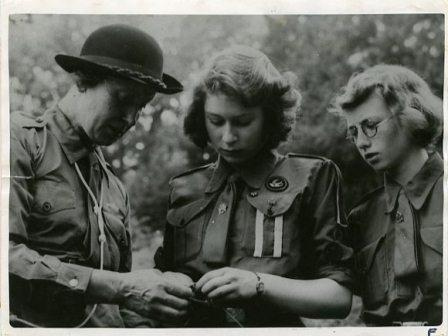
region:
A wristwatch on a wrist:
[247, 269, 270, 303]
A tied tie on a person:
[194, 155, 256, 272]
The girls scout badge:
[262, 171, 294, 195]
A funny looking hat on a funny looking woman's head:
[50, 39, 185, 156]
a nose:
[220, 119, 244, 148]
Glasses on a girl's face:
[344, 115, 379, 143]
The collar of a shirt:
[201, 147, 289, 198]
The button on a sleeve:
[66, 273, 80, 292]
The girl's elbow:
[319, 280, 356, 322]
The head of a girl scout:
[331, 64, 447, 190]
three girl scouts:
[11, 21, 446, 331]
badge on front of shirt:
[263, 171, 293, 193]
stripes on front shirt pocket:
[246, 204, 290, 260]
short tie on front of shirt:
[193, 171, 244, 267]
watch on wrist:
[243, 268, 266, 300]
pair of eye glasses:
[339, 104, 404, 148]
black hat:
[44, 21, 187, 99]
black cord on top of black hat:
[93, 58, 173, 92]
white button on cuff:
[62, 272, 82, 291]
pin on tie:
[213, 199, 231, 219]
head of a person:
[57, 26, 168, 152]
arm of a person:
[248, 277, 347, 324]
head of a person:
[168, 45, 311, 175]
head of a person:
[338, 83, 426, 168]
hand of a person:
[140, 247, 209, 314]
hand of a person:
[183, 250, 260, 318]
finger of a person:
[153, 275, 199, 330]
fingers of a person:
[209, 257, 246, 307]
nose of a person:
[125, 110, 142, 122]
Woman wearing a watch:
[241, 263, 265, 305]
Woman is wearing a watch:
[250, 264, 267, 305]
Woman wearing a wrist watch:
[247, 267, 266, 302]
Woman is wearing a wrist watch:
[245, 264, 268, 303]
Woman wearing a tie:
[382, 182, 427, 282]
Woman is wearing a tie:
[390, 184, 422, 288]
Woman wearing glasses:
[342, 105, 404, 144]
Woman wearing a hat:
[53, 16, 188, 97]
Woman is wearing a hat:
[48, 20, 190, 98]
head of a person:
[61, 29, 173, 160]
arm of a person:
[16, 229, 161, 316]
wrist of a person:
[105, 258, 141, 313]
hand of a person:
[123, 252, 199, 319]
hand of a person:
[206, 255, 259, 306]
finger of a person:
[201, 243, 242, 304]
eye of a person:
[192, 106, 265, 134]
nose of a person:
[218, 116, 246, 147]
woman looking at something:
[150, 70, 347, 320]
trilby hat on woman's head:
[63, 33, 192, 92]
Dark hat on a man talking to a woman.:
[52, 24, 187, 95]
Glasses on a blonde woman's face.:
[345, 115, 395, 138]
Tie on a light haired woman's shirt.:
[389, 186, 428, 283]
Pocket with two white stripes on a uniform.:
[243, 191, 299, 257]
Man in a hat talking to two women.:
[5, 24, 185, 323]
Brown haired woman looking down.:
[158, 49, 354, 328]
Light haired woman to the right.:
[328, 65, 438, 326]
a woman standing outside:
[29, 21, 186, 332]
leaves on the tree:
[430, 42, 446, 74]